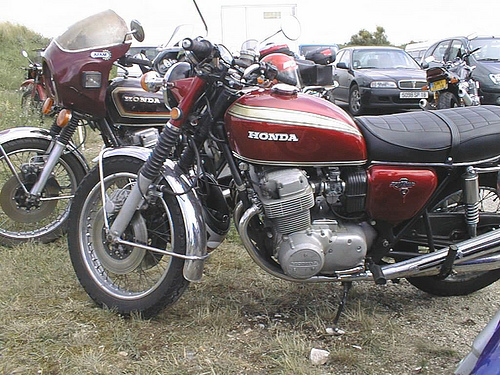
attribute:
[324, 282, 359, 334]
stand — kick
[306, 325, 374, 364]
rocks — gray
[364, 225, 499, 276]
pipe — chrome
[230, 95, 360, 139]
stripe — tan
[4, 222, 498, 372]
grass — dry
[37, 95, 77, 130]
lights — orange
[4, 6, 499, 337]
bikes — couple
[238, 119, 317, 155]
honda — word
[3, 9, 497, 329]
lot — parking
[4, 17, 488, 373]
grass — green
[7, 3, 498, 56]
sky — white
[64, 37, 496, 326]
bike — red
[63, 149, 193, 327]
wheel — black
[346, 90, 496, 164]
seat — black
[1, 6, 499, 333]
motorcycles — parked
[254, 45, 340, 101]
helmet — red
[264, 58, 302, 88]
shield — face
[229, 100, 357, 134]
stripe — gold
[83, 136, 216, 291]
fender — chrome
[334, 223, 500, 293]
muffler — chrome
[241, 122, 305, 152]
honda — written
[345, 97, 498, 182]
seat — black, leather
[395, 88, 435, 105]
license plate — white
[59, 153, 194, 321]
tire — round, black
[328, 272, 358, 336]
kickstand — down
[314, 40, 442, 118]
car — parked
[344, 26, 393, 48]
leaves — green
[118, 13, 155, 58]
mirror — round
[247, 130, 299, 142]
honda — white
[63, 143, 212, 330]
wheel — black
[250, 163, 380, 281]
motor — gray